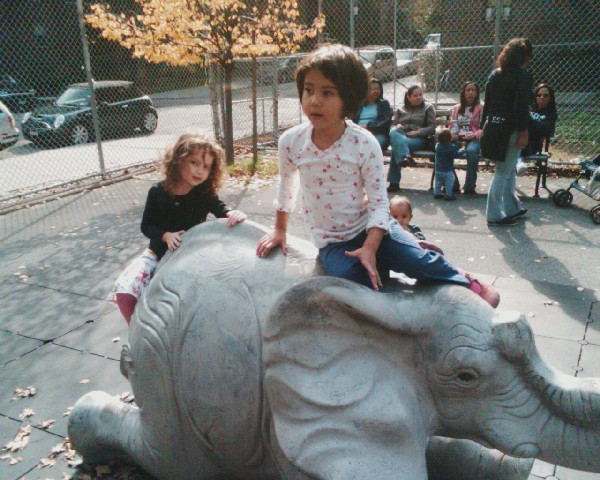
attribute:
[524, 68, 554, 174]
woman — standing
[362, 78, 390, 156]
person — sitting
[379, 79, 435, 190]
person — sitting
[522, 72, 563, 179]
person — sitting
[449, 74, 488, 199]
person — sitting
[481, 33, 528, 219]
person — standing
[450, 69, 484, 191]
person — standing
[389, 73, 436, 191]
person — standing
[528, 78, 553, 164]
person — sitting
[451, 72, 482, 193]
person — sitting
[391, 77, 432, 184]
person — sitting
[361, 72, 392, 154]
person — sitting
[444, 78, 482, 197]
person — sitting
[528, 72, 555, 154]
person — sitting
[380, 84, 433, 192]
person — sitting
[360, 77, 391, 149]
person — sitting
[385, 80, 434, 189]
person — sitting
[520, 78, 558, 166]
person — sitting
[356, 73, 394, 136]
person — sitting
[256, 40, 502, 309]
person — sitting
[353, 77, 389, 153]
person — sitting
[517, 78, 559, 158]
person — sitting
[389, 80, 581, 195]
people — sitting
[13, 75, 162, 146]
car — parked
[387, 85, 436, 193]
person — sitting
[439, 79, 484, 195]
person — sitting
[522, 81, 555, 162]
person — sitting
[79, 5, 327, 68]
leaves — brown